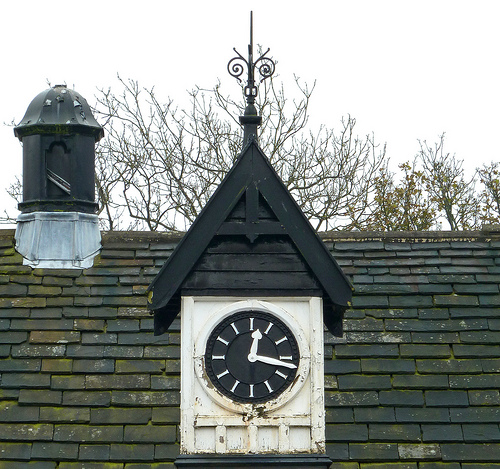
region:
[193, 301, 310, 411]
clock is color black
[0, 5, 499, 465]
branches behind a roof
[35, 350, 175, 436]
moss under the roof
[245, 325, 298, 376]
handles of clock is white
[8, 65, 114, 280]
a chimney over the roof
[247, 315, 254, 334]
white line on clock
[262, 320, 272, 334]
white line on clock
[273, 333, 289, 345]
white line on clock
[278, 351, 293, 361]
white line on clock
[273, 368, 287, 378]
white line on clock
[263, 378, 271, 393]
white line on clock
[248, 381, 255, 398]
white line on clock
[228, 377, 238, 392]
white line on clock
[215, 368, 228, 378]
white line on clock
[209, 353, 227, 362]
white line on clock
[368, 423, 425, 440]
a tile on a roof of a building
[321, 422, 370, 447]
a tile on a roof of a building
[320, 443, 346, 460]
a tile on a roof of a building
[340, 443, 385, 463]
a tile on a roof of a building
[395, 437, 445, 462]
a tile on a roof of a building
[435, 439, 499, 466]
a tile on a roof of a building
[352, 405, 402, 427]
a tile on a roof of a building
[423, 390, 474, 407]
a tile on a roof of a building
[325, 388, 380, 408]
a tile on a roof of a building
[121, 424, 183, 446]
a tile on a roof of a building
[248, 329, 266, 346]
hand on the clock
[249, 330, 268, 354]
hand on the clock is white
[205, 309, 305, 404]
clock is black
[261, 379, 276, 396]
number is white on the clock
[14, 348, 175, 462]
roof tiles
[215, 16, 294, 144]
a pointy top to the clock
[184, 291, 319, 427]
clock is black and white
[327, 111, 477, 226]
trees in the background up above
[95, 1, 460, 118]
bright white sky up above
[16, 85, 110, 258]
a black top to the roof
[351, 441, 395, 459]
a tile on the roof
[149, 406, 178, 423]
a tile on the roof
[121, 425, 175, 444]
a tile on the roof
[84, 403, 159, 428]
a tile on the roof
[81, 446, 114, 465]
a tile on the roof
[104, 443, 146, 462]
a tile on the roof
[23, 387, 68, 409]
a tile on the roof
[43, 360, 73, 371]
a tile on the roof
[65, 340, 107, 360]
a tile on the roof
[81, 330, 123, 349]
a tile on the roof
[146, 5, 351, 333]
black triangle with curlicue on rooftop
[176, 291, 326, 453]
black clock set into white square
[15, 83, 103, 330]
domed cylinder on top of roofing tiles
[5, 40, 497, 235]
bare branches and leafing branches behind roof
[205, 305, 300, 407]
clock is on the tower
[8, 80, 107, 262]
chimney is on the top of the roof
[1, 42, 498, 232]
trees are behind the roof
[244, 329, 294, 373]
clock hands are white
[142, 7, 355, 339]
roof is above clock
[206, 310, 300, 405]
clock is black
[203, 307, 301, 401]
clock is at the top of the tower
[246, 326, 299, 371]
hands are apart of the clock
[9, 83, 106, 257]
chimney is on top of the roof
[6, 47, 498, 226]
trees are behind the building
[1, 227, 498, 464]
the roof is black and mossy